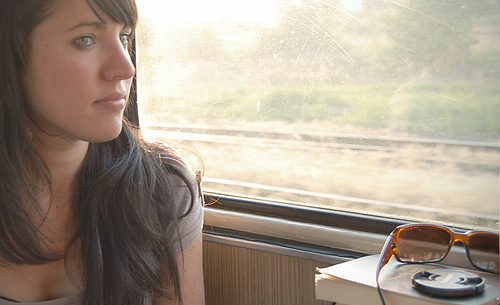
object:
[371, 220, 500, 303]
glasses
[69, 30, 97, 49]
eye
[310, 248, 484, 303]
book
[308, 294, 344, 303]
shelf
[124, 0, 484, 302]
train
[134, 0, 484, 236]
window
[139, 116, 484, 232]
tracks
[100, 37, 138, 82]
nose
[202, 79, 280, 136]
bushes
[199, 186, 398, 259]
bottom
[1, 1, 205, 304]
female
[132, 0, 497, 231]
train window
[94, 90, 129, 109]
lips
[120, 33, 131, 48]
eyes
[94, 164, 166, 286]
hair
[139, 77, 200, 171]
sun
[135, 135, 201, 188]
girl`s shoulder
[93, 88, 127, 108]
mouth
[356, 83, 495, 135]
bushes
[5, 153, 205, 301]
shirt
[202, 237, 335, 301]
wall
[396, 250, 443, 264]
light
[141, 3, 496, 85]
trees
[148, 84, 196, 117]
bushes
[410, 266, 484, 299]
lid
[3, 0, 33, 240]
hair